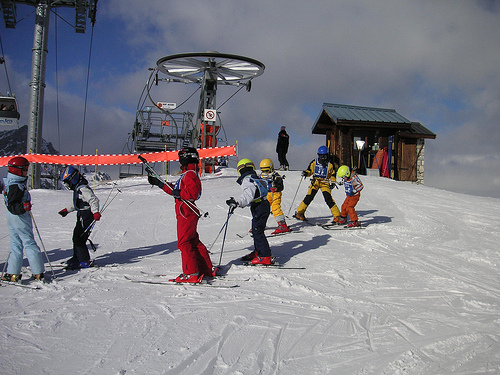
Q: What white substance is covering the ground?
A: Snow.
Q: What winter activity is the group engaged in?
A: Skiing.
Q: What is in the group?
A: The seven skiers.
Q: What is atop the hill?
A: Small wooden house.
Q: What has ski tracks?
A: The snow.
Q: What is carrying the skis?
A: The skier with the red suit.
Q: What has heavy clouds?
A: The blue sky.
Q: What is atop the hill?
A: The ski lift.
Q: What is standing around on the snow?
A: The group of skiers.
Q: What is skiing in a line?
A: The children.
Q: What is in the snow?
A: Ski tracks.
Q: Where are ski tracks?
A: In the snow.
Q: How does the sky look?
A: Cloudy.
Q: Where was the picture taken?
A: On a ski slope.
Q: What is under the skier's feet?
A: Skis.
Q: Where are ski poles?
A: In skier's hands.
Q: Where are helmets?
A: On the skier's heads.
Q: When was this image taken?
A: Daytime.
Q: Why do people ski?
A: Recreation.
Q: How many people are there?
A: Eight.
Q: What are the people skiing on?
A: Snow.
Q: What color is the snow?
A: White.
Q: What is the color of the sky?
A: Blue.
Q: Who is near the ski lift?
A: The ski lift attendant.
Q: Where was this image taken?
A: Mountain.